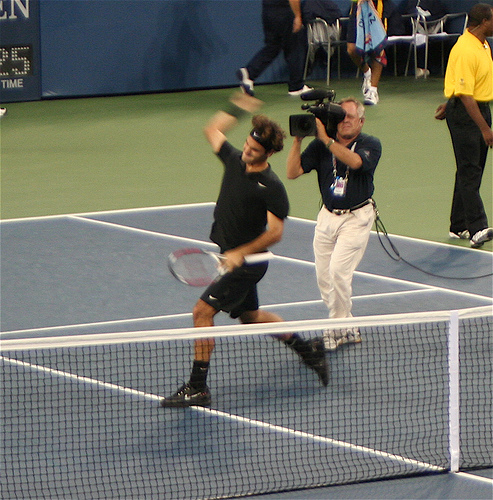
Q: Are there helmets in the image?
A: No, there are no helmets.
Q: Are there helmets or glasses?
A: No, there are no helmets or glasses.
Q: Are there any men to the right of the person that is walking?
A: Yes, there is a man to the right of the person.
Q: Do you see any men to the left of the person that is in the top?
A: No, the man is to the right of the person.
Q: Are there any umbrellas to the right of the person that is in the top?
A: No, there is a man to the right of the person.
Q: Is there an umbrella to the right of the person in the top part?
A: No, there is a man to the right of the person.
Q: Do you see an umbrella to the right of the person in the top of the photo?
A: No, there is a man to the right of the person.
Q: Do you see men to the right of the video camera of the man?
A: Yes, there is a man to the right of the video camera.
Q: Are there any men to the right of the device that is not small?
A: Yes, there is a man to the right of the video camera.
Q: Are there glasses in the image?
A: No, there are no glasses.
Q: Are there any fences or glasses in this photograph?
A: No, there are no glasses or fences.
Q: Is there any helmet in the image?
A: No, there are no helmets.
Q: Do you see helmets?
A: No, there are no helmets.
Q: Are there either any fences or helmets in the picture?
A: No, there are no helmets or fences.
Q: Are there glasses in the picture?
A: No, there are no glasses.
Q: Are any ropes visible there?
A: No, there are no ropes.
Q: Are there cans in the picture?
A: No, there are no cans.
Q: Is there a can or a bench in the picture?
A: No, there are no cans or benches.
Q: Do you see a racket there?
A: Yes, there is a racket.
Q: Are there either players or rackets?
A: Yes, there is a racket.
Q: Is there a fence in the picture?
A: No, there are no fences.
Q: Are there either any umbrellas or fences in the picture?
A: No, there are no fences or umbrellas.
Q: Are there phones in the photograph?
A: No, there are no phones.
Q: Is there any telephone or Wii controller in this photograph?
A: No, there are no phones or Wii controllers.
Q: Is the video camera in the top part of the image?
A: Yes, the video camera is in the top of the image.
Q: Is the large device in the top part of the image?
A: Yes, the video camera is in the top of the image.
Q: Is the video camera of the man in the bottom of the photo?
A: No, the video camera is in the top of the image.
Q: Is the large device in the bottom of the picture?
A: No, the video camera is in the top of the image.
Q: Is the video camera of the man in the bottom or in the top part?
A: The video camera is in the top of the image.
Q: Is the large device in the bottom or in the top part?
A: The video camera is in the top of the image.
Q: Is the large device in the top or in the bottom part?
A: The video camera is in the top of the image.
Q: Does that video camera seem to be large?
A: Yes, the video camera is large.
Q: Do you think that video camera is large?
A: Yes, the video camera is large.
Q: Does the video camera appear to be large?
A: Yes, the video camera is large.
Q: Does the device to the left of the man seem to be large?
A: Yes, the video camera is large.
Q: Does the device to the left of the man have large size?
A: Yes, the video camera is large.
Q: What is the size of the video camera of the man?
A: The video camera is large.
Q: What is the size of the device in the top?
A: The video camera is large.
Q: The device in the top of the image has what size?
A: The video camera is large.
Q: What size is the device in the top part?
A: The video camera is large.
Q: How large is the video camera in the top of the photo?
A: The video camera is large.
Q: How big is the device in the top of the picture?
A: The video camera is large.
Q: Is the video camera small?
A: No, the video camera is large.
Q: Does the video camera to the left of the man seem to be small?
A: No, the video camera is large.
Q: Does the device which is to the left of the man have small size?
A: No, the video camera is large.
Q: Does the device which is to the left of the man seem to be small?
A: No, the video camera is large.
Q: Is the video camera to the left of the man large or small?
A: The video camera is large.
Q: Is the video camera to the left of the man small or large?
A: The video camera is large.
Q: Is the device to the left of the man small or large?
A: The video camera is large.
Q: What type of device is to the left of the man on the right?
A: The device is a video camera.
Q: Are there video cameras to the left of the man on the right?
A: Yes, there is a video camera to the left of the man.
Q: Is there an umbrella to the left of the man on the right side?
A: No, there is a video camera to the left of the man.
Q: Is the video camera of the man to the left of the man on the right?
A: Yes, the video camera is to the left of the man.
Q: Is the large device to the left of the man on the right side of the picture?
A: Yes, the video camera is to the left of the man.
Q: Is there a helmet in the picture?
A: No, there are no helmets.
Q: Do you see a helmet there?
A: No, there are no helmets.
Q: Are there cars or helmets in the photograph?
A: No, there are no helmets or cars.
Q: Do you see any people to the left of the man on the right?
A: Yes, there is a person to the left of the man.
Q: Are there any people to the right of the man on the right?
A: No, the person is to the left of the man.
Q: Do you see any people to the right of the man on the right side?
A: No, the person is to the left of the man.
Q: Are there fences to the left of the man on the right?
A: No, there is a person to the left of the man.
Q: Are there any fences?
A: No, there are no fences.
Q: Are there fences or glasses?
A: No, there are no fences or glasses.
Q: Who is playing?
A: The man is playing.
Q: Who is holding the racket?
A: The man is holding the racket.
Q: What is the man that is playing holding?
A: The man is holding the tennis racket.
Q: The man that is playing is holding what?
A: The man is holding the tennis racket.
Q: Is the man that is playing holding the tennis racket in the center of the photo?
A: Yes, the man is holding the racket.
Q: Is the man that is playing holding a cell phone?
A: No, the man is holding the racket.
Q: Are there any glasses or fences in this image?
A: No, there are no fences or glasses.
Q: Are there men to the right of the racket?
A: Yes, there is a man to the right of the racket.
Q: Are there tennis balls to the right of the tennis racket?
A: No, there is a man to the right of the tennis racket.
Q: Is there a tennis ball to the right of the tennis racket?
A: No, there is a man to the right of the tennis racket.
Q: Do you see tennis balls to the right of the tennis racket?
A: No, there is a man to the right of the tennis racket.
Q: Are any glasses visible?
A: No, there are no glasses.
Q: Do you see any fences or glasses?
A: No, there are no glasses or fences.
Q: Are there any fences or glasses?
A: No, there are no glasses or fences.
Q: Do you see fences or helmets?
A: No, there are no helmets or fences.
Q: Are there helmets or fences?
A: No, there are no helmets or fences.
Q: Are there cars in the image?
A: No, there are no cars.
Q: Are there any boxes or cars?
A: No, there are no cars or boxes.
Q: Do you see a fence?
A: No, there are no fences.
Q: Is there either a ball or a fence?
A: No, there are no fences or balls.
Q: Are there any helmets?
A: No, there are no helmets.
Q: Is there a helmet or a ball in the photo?
A: No, there are no helmets or balls.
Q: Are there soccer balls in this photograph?
A: No, there are no soccer balls.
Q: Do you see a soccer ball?
A: No, there are no soccer balls.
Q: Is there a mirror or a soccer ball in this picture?
A: No, there are no soccer balls or mirrors.